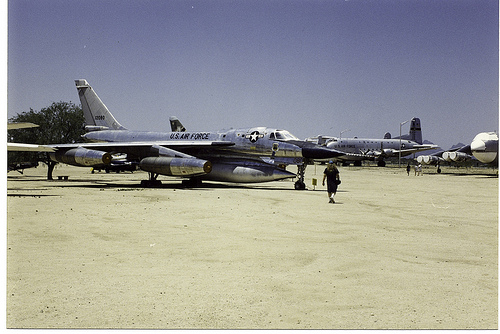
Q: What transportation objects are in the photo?
A: Airplanes.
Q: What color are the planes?
A: Blue.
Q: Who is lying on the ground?
A: No one.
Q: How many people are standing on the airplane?
A: Zero.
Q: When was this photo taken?
A: Daytime.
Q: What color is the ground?
A: Tan.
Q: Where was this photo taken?
A: At an airport.